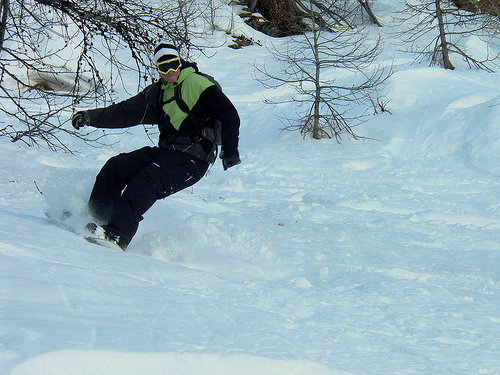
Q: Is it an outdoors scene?
A: Yes, it is outdoors.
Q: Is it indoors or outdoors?
A: It is outdoors.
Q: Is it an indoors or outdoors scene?
A: It is outdoors.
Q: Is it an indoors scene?
A: No, it is outdoors.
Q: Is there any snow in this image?
A: Yes, there is snow.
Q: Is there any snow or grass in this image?
A: Yes, there is snow.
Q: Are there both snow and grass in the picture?
A: No, there is snow but no grass.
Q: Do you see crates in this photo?
A: No, there are no crates.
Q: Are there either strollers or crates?
A: No, there are no crates or strollers.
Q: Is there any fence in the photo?
A: No, there are no fences.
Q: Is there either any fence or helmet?
A: No, there are no fences or helmets.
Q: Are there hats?
A: Yes, there is a hat.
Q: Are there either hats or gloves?
A: Yes, there is a hat.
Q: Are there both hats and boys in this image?
A: No, there is a hat but no boys.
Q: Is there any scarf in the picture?
A: No, there are no scarves.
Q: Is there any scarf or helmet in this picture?
A: No, there are no scarves or helmets.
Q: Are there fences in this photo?
A: No, there are no fences.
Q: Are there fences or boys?
A: No, there are no fences or boys.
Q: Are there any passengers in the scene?
A: No, there are no passengers.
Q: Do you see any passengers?
A: No, there are no passengers.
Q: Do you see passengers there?
A: No, there are no passengers.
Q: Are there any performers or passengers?
A: No, there are no passengers or performers.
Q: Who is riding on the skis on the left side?
A: The man is riding on the skis.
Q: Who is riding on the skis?
A: The man is riding on the skis.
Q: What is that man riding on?
A: The man is riding on the skis.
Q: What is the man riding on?
A: The man is riding on the skis.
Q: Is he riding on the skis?
A: Yes, the man is riding on the skis.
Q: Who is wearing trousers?
A: The man is wearing trousers.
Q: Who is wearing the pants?
A: The man is wearing trousers.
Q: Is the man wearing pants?
A: Yes, the man is wearing pants.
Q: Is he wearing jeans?
A: No, the man is wearing pants.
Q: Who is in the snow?
A: The man is in the snow.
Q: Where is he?
A: The man is in the snow.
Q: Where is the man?
A: The man is in the snow.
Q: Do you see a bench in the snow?
A: No, there is a man in the snow.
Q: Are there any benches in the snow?
A: No, there is a man in the snow.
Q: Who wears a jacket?
A: The man wears a jacket.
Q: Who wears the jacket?
A: The man wears a jacket.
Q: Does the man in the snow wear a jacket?
A: Yes, the man wears a jacket.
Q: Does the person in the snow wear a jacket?
A: Yes, the man wears a jacket.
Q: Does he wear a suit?
A: No, the man wears a jacket.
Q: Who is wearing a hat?
A: The man is wearing a hat.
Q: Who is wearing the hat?
A: The man is wearing a hat.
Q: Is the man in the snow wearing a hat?
A: Yes, the man is wearing a hat.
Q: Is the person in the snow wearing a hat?
A: Yes, the man is wearing a hat.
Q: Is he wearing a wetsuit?
A: No, the man is wearing a hat.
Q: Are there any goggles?
A: Yes, there are goggles.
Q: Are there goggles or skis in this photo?
A: Yes, there are goggles.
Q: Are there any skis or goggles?
A: Yes, there are goggles.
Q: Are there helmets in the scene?
A: No, there are no helmets.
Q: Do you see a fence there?
A: No, there are no fences.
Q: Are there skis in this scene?
A: Yes, there are skis.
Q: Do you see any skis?
A: Yes, there are skis.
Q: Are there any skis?
A: Yes, there are skis.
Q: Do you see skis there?
A: Yes, there are skis.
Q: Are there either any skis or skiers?
A: Yes, there are skis.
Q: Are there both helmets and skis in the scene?
A: No, there are skis but no helmets.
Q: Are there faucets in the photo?
A: No, there are no faucets.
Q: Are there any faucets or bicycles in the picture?
A: No, there are no faucets or bicycles.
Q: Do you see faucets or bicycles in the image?
A: No, there are no faucets or bicycles.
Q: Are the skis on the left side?
A: Yes, the skis are on the left of the image.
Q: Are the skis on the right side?
A: No, the skis are on the left of the image.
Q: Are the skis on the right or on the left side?
A: The skis are on the left of the image.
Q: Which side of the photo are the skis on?
A: The skis are on the left of the image.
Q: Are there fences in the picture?
A: No, there are no fences.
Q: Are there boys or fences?
A: No, there are no fences or boys.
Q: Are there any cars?
A: No, there are no cars.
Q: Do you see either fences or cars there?
A: No, there are no cars or fences.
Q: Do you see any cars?
A: No, there are no cars.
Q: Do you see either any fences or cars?
A: No, there are no cars or fences.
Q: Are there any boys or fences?
A: No, there are no fences or boys.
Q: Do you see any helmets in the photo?
A: No, there are no helmets.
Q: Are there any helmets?
A: No, there are no helmets.